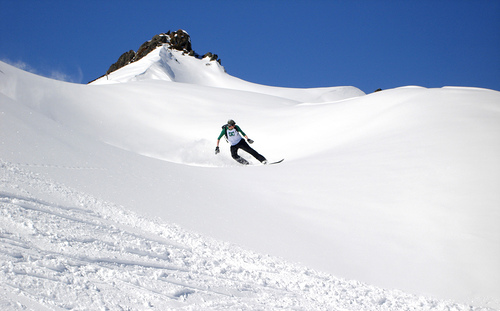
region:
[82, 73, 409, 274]
the snow is white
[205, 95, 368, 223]
the man is snowboarding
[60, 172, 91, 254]
tracks were in the snow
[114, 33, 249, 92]
the mountain tops do not have snow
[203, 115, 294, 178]
the man has dark pants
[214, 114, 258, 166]
the man is wearing a helmet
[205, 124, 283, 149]
the man has a green and white shirt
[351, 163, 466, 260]
ground covered in snow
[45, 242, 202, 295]
ski tracks in snow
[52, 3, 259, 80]
mountain covered in thick snow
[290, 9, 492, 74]
clear blue cloudless sky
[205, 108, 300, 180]
snow boarder riding snowboard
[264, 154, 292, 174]
tip of snowboard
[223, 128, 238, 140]
writing on front of shirt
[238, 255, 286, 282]
clumps of white snow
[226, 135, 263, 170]
person wearing black pants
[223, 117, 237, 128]
person wearing a green helmet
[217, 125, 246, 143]
person wearing a white and green shirt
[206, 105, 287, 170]
person skiing down the slope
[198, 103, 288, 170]
person skiing down the slope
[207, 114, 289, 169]
person skiing down the slope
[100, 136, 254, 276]
ground covered in snow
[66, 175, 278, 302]
ground covered in white snow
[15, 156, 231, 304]
snow covering the ground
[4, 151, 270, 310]
white snow covering the ground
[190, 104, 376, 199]
a man that is snowboarding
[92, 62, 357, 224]
a man snowboarding on the snow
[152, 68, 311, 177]
a man snowboarding on the white snow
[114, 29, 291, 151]
a mountain covered in snow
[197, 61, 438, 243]
a man on the snow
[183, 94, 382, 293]
a man on the white snow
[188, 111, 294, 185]
a person skiing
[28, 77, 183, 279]
white snow on the ground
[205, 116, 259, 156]
a person wearing gloves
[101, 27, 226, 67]
hill with partial snow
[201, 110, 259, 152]
a person wearing a green and white top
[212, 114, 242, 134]
person wearing a hat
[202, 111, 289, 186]
a person outside in the snow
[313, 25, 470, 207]
snow on the ground and clear skies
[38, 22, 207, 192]
hilly landscape with snow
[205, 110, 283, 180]
person skiing with black pants